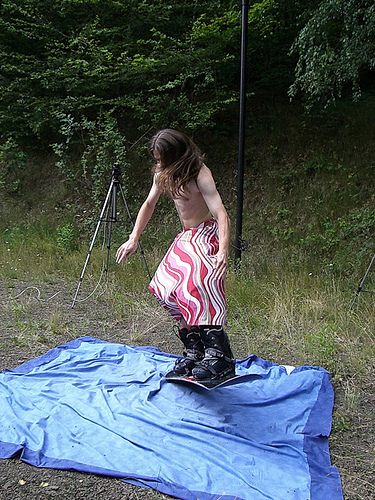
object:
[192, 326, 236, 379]
boots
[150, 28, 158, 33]
leaves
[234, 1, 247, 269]
pole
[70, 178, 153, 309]
tripod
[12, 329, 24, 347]
grass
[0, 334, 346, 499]
blanket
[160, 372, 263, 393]
snowboard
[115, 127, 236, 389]
man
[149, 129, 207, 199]
hair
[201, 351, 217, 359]
buckles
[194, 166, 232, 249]
arm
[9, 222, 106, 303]
wire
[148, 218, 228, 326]
skirt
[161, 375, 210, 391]
nose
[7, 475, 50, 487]
stones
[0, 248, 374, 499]
ground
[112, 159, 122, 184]
camera